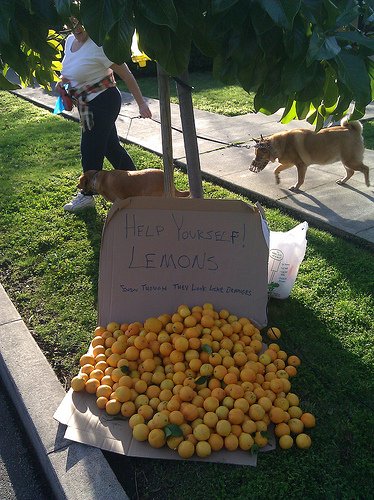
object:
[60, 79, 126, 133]
shirt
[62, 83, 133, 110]
waist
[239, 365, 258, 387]
lemon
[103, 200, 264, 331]
sign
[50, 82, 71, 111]
bag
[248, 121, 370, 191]
dog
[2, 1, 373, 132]
tree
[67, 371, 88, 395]
lemons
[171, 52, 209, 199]
pole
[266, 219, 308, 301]
plastic bag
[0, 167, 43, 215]
grass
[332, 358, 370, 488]
grass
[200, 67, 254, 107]
grass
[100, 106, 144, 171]
leash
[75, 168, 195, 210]
dog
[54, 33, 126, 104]
shirt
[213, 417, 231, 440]
lemons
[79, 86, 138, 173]
pants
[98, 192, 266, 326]
box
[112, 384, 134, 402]
lemons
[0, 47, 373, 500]
ground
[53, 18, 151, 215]
woman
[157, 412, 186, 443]
leaves